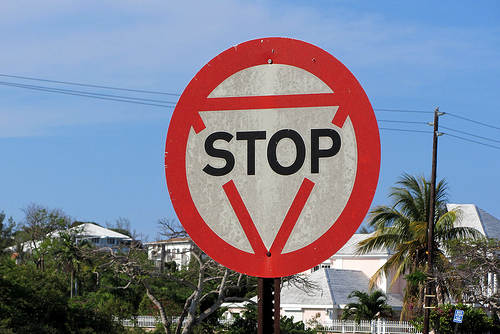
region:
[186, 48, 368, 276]
stop sign is red, white and black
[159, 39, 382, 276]
stop sign is circular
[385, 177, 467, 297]
palm tree in background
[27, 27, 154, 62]
sky is blue with little clouds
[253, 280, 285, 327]
sign has metal pole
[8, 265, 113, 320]
green tree leaves on trees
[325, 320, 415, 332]
white picket fence in background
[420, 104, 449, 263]
electrical pole is wooden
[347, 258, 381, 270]
house wall is pink colored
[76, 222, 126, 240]
house roof is white in colored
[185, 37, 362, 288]
red white and black sign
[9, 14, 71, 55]
white clouds in blue sky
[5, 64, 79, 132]
white clouds in blue sky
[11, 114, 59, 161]
white clouds in blue sky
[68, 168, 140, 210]
white clouds in blue sky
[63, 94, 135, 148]
white clouds in blue sky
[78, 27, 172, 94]
white clouds in blue sky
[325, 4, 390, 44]
white clouds in blue sky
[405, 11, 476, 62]
white clouds in blue sky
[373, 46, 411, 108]
white clouds in blue sky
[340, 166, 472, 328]
two palm trees, one very tall and one short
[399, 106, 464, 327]
tall brown telephone pole with three strings running off of it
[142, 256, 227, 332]
tree which appears dead with grey bark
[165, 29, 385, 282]
large round sign that says stop in the middle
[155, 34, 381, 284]
round sign with broken triangle in the middle and has the word stop going through it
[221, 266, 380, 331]
house with light pink main color and white trim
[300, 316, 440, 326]
white fence around housing area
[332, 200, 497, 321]
large light pink house with light gray roof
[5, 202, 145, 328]
trees obscuring view of light blue house with white roof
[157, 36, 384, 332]
stop sign with brown metal sign post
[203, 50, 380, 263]
stop sign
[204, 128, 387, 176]
black writing on sign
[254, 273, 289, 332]
metal with four circular dots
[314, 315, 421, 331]
white picket fence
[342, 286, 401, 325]
palm tree with green leaves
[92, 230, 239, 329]
barren tree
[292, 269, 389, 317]
white rooftop shingles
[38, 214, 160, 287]
house surrounded by trees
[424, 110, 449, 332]
wooden pole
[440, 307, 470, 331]
blue and white sign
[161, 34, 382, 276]
a stop sign in a town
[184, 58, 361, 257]
the center of the stop sign is white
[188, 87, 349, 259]
a triangle in the stop sign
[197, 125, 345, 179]
the letters are black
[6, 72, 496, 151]
power lines behind the stop sign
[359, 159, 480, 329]
a palm tree below the power lines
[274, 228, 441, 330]
a house by the palm tree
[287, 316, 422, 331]
a white fence by the house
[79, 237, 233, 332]
a tree by the stop sign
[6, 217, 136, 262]
a house behind the trees